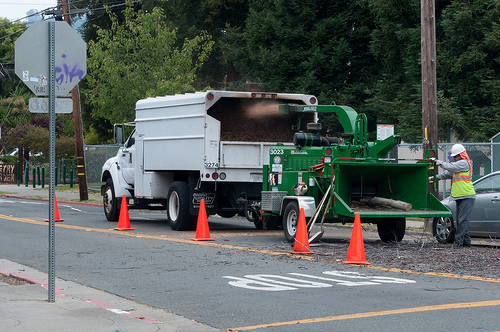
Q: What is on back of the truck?
A: Chipper trailer.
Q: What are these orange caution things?
A: Cones.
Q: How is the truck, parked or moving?
A: Parked.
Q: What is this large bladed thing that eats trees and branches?
A: Wood Chipper.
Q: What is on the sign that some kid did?
A: Graffiti.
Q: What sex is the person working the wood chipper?
A: Male.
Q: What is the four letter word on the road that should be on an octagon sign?
A: STOP.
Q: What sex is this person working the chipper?
A: Male.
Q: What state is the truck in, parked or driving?
A: Parked.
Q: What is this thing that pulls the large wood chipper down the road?
A: Truck.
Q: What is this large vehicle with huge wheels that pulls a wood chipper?
A: Truck.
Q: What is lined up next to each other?
A: Orange cones.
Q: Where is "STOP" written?
A: On the road.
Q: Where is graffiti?
A: On back of a sign.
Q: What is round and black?
A: Tires.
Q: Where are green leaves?
A: On trees.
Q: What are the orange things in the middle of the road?
A: Cones.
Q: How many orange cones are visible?
A: Five.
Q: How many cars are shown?
A: One.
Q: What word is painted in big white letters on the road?
A: Stop.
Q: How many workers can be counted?
A: One.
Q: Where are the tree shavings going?
A: Truck.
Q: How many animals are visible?
A: Zero.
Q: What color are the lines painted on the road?
A: Yellow.